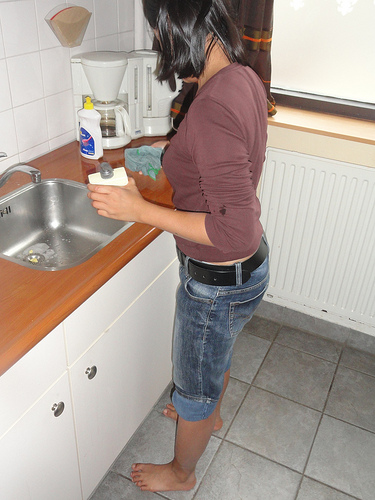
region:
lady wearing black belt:
[174, 242, 260, 296]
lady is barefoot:
[107, 397, 250, 496]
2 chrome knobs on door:
[25, 347, 120, 439]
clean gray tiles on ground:
[252, 359, 353, 486]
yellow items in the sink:
[21, 225, 55, 286]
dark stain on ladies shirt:
[188, 199, 236, 225]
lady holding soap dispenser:
[77, 151, 141, 217]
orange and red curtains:
[210, 27, 276, 52]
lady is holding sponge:
[121, 137, 179, 183]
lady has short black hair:
[148, 25, 295, 89]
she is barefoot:
[114, 388, 246, 493]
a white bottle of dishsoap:
[73, 88, 111, 165]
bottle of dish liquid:
[61, 93, 110, 169]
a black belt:
[177, 247, 281, 295]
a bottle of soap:
[79, 158, 165, 207]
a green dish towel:
[121, 134, 171, 185]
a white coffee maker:
[67, 39, 148, 163]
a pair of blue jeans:
[162, 250, 288, 434]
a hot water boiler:
[130, 43, 181, 141]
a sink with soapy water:
[1, 153, 124, 275]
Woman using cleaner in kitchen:
[2, 1, 367, 496]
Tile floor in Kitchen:
[250, 319, 374, 492]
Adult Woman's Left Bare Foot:
[127, 460, 197, 493]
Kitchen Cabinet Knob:
[50, 399, 66, 416]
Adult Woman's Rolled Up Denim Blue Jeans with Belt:
[169, 246, 274, 421]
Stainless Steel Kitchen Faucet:
[1, 162, 42, 187]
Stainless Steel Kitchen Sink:
[2, 174, 109, 272]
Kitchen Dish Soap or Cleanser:
[76, 94, 106, 160]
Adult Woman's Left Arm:
[87, 178, 207, 237]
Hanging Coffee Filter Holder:
[39, 1, 93, 49]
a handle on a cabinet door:
[68, 341, 116, 387]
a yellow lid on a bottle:
[81, 88, 96, 113]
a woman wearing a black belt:
[182, 251, 261, 291]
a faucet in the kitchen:
[3, 156, 58, 190]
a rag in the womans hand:
[117, 133, 169, 184]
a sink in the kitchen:
[20, 234, 72, 264]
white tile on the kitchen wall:
[9, 37, 56, 116]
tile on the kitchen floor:
[280, 362, 338, 457]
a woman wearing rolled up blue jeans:
[156, 369, 236, 436]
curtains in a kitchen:
[241, 15, 284, 96]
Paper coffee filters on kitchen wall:
[39, 2, 97, 51]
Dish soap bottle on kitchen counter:
[75, 94, 107, 160]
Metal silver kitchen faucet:
[1, 142, 46, 196]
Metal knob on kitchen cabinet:
[73, 362, 100, 381]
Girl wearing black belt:
[166, 233, 281, 290]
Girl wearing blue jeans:
[163, 237, 282, 433]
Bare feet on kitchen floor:
[127, 386, 246, 498]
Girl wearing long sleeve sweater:
[155, 58, 278, 269]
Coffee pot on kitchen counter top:
[64, 46, 145, 151]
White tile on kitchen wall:
[10, 48, 53, 121]